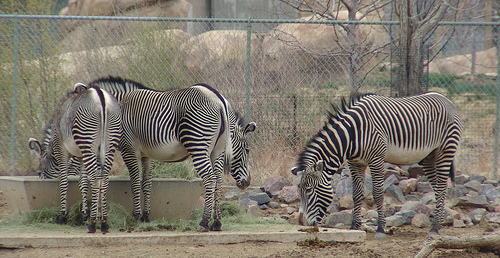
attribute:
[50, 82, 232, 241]
zebras — in zoo, eating, together, black, striped, grazing, feeding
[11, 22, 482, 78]
fence — chain-link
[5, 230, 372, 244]
concrete — slab, ground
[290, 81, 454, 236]
zebra — eating, alone, grazing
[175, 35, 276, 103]
rock — pink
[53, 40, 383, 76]
rocks — piled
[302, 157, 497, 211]
rocks — grey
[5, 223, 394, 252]
platform — concrete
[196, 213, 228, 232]
feet — black